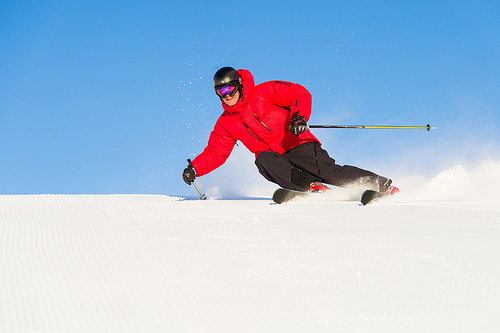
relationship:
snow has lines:
[0, 27, 499, 332] [0, 194, 499, 332]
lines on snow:
[0, 194, 499, 332] [0, 27, 499, 332]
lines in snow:
[0, 194, 499, 332] [0, 27, 499, 332]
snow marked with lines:
[0, 27, 499, 332] [0, 194, 499, 332]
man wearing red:
[183, 66, 401, 204] [190, 69, 401, 196]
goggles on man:
[214, 80, 243, 99] [183, 66, 401, 204]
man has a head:
[183, 66, 401, 204] [214, 66, 242, 106]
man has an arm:
[183, 66, 401, 204] [183, 118, 238, 183]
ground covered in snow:
[1, 194, 500, 331] [0, 27, 499, 332]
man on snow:
[183, 66, 401, 204] [0, 27, 499, 332]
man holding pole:
[183, 66, 401, 204] [309, 125, 438, 132]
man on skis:
[183, 66, 401, 204] [273, 185, 391, 206]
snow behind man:
[198, 148, 500, 197] [183, 66, 401, 204]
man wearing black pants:
[183, 66, 401, 204] [254, 141, 392, 194]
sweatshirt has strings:
[190, 69, 322, 158] [227, 100, 271, 137]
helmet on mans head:
[214, 67, 242, 88] [214, 66, 242, 106]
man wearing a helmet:
[183, 66, 401, 204] [214, 67, 242, 88]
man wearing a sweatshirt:
[183, 66, 401, 204] [190, 69, 322, 158]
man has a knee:
[183, 66, 401, 204] [255, 150, 278, 171]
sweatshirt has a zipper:
[190, 69, 322, 158] [251, 112, 272, 134]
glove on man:
[289, 116, 307, 137] [183, 66, 401, 204]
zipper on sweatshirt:
[251, 112, 272, 134] [190, 69, 322, 158]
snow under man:
[0, 27, 499, 332] [183, 66, 401, 204]